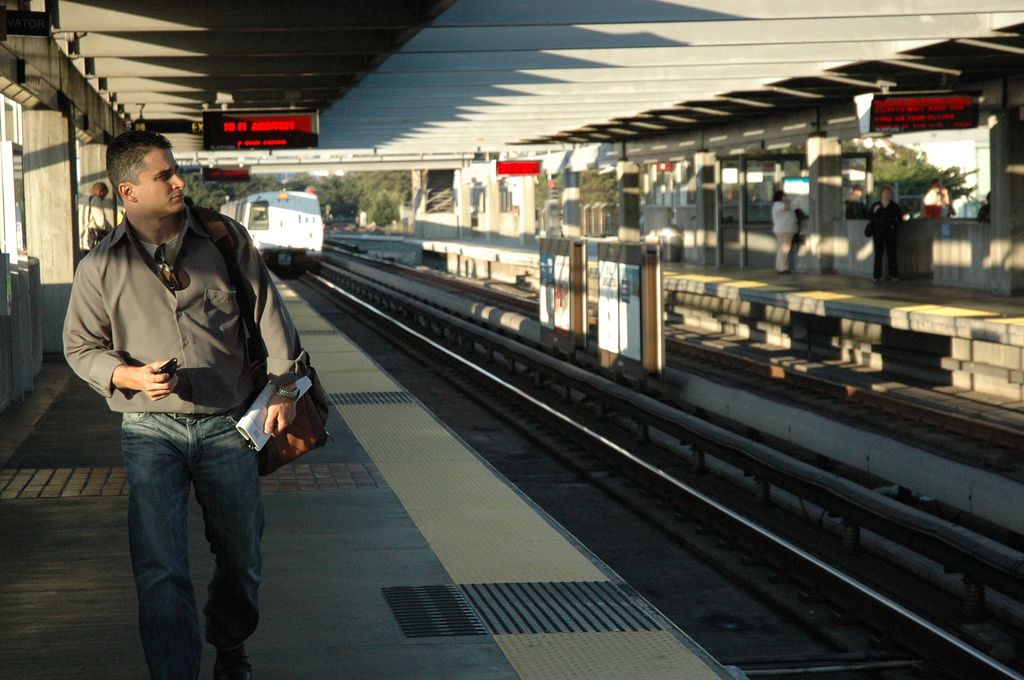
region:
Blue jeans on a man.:
[104, 399, 270, 676]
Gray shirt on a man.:
[56, 215, 310, 428]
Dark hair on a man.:
[106, 121, 198, 236]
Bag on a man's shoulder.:
[163, 195, 337, 480]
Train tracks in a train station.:
[262, 230, 974, 671]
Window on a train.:
[245, 190, 274, 238]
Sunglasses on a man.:
[142, 222, 185, 293]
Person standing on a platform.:
[765, 183, 804, 267]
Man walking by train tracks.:
[65, 117, 315, 662]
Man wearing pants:
[100, 384, 288, 676]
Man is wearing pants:
[106, 381, 302, 676]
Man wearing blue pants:
[114, 381, 282, 673]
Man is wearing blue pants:
[98, 393, 269, 673]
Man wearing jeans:
[108, 381, 285, 673]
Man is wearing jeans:
[106, 396, 288, 676]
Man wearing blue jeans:
[115, 387, 284, 675]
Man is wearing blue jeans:
[103, 393, 287, 676]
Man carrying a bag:
[178, 185, 353, 492]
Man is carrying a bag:
[179, 172, 361, 483]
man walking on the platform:
[59, 134, 374, 678]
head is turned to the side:
[109, 134, 192, 224]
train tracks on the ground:
[264, 225, 1023, 678]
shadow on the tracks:
[807, 355, 883, 388]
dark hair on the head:
[103, 137, 162, 191]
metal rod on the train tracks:
[308, 264, 1023, 670]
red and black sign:
[195, 98, 326, 152]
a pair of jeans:
[125, 389, 299, 678]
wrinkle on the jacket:
[176, 298, 243, 356]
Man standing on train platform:
[73, 130, 326, 677]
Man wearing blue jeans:
[73, 117, 318, 672]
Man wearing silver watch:
[68, 120, 332, 664]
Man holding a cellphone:
[65, 119, 332, 667]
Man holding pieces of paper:
[72, 111, 351, 665]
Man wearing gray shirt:
[53, 116, 354, 647]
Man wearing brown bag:
[65, 132, 369, 674]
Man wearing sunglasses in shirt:
[70, 126, 343, 664]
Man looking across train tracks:
[60, 124, 364, 666]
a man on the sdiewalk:
[15, 81, 276, 511]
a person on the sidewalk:
[746, 163, 829, 265]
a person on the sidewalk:
[844, 176, 947, 291]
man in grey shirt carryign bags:
[45, 101, 341, 677]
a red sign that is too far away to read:
[479, 145, 547, 180]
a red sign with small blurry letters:
[840, 77, 990, 138]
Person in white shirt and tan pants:
[760, 178, 805, 280]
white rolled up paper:
[226, 352, 324, 452]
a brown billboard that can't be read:
[527, 219, 589, 349]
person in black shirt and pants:
[854, 177, 915, 291]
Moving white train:
[210, 183, 335, 276]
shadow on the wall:
[874, 322, 960, 386]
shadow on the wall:
[778, 308, 836, 354]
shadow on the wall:
[743, 293, 767, 344]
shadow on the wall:
[514, 267, 534, 283]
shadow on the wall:
[807, 153, 852, 277]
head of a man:
[115, 141, 195, 215]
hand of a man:
[125, 353, 184, 399]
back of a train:
[242, 185, 319, 266]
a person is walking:
[50, 119, 250, 434]